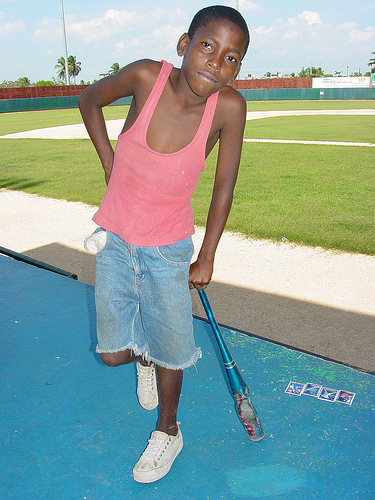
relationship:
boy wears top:
[75, 3, 251, 484] [90, 56, 220, 248]